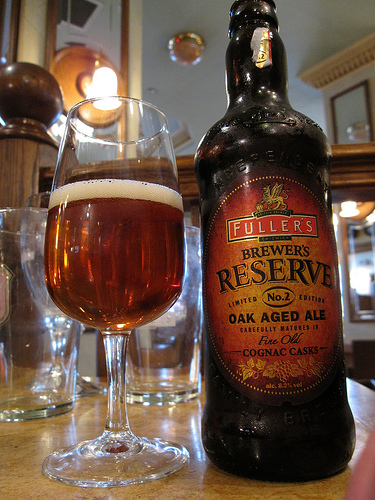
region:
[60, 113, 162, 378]
wine glass of beer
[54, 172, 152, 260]
beer in a wine glass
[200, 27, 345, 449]
bottle of Fuller's ale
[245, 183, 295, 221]
Griffon on beer label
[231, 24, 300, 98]
sticker on beer bottle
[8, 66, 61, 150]
wooden knob on rail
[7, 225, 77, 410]
empty Pilsner glass on table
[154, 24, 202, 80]
light fixture on ceiling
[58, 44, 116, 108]
glowing fixture on wall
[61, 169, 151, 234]
white head on beer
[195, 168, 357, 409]
label on side of glass bottle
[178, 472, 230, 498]
brown cover of table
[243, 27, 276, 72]
half peeled label on bottle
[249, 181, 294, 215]
design on side of glass bottle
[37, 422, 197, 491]
glass base of drinking glass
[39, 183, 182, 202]
foam on top of beer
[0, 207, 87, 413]
clear glass drinking glass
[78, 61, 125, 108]
light on wall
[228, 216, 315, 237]
company name on beer bottle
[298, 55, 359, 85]
design on moulding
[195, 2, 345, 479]
brown bottle of beer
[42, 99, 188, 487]
clear glass with beer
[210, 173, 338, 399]
lable on beer bottle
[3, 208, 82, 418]
empty clear drinking glass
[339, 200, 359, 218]
light hanging on ceiling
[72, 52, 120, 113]
light hanging on plaque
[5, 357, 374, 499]
brown wood dinner table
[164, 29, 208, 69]
light hanging on ceiling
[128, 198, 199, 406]
empty glass on table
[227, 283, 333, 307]
BOTTLE IS LIMITED NO. 2 EDITION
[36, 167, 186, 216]
FOAM HEAD ON GLASS OF ALE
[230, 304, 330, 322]
BEVERAGE IS OAK AGED ALE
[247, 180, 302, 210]
FLYING LION ON TOP OF LABEL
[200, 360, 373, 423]
BREWED IN A FAMILY BREWERY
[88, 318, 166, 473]
BEER GLASS HAS A STEM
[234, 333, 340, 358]
MATURED IN A FINE OLD COGNAC CASKS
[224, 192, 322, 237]
FULLER'S IS THE NAME OF THE BREWERY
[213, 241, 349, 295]
IT IS A BREWER'S RESERVE ALE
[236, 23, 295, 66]
TOP LABEL HAS BEEN TORN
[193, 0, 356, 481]
a bottle of beer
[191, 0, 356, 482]
Fuller's brand of Brewer's Reserve beer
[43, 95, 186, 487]
beer in a glass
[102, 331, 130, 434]
the stem of a glass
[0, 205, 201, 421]
two empty glasses behind the glass of beer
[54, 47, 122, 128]
light fixture on the wall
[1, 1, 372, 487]
three glasses and a beer bottle on the table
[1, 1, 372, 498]
the inside of a bar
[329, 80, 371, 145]
a mirror on the wall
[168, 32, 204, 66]
a light fixture on the ceiling